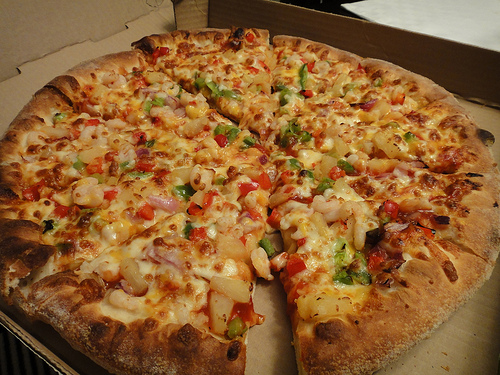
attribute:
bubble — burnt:
[312, 319, 348, 344]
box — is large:
[2, 8, 487, 356]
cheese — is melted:
[327, 188, 354, 223]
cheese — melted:
[146, 254, 220, 325]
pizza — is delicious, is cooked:
[7, 27, 497, 371]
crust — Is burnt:
[0, 214, 55, 286]